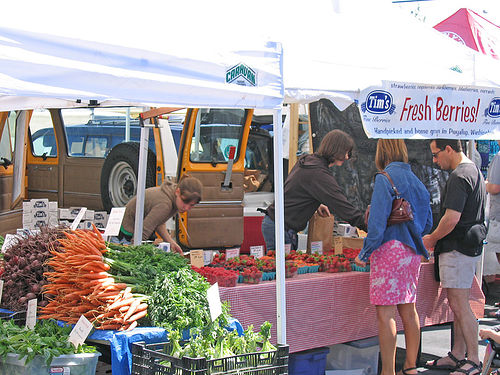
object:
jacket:
[357, 162, 434, 262]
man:
[419, 140, 489, 374]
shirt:
[432, 161, 489, 257]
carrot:
[120, 299, 141, 323]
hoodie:
[122, 175, 178, 241]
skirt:
[366, 239, 426, 307]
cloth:
[202, 258, 486, 354]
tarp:
[0, 306, 246, 374]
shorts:
[436, 250, 482, 290]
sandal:
[446, 359, 481, 374]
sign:
[358, 89, 397, 116]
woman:
[352, 138, 431, 375]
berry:
[263, 249, 276, 257]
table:
[189, 245, 486, 368]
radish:
[16, 295, 28, 304]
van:
[12, 106, 274, 256]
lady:
[261, 129, 368, 254]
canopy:
[0, 0, 499, 344]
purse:
[362, 170, 414, 226]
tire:
[98, 141, 157, 215]